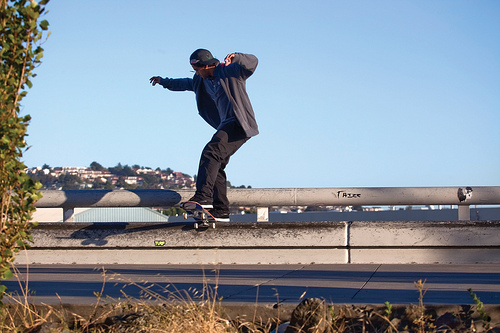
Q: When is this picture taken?
A: Daytime.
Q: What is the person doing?
A: Skateboarding.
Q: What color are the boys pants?
A: Black.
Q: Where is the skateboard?
A: Under boys feet.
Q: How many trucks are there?
A: None.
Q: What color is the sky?
A: Blue.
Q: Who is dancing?
A: No one.